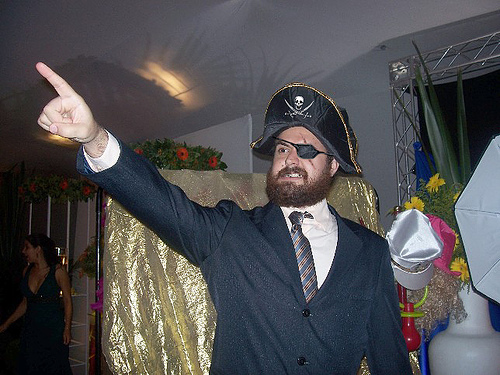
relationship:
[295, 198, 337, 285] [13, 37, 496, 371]
white shirt in photo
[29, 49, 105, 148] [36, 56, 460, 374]
hand of person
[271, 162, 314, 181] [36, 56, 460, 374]
mouth of person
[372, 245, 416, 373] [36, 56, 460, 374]
arm of person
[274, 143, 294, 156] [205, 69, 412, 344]
eye of person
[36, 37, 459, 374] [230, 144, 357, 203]
person wearing beard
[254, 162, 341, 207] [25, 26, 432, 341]
beard on person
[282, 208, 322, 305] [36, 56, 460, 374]
tie on person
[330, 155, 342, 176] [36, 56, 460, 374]
ear on person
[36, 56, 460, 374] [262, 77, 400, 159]
person wearing hat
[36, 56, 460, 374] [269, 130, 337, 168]
person wearing eye patch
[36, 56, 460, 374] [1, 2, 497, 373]
person inside house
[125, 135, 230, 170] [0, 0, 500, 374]
decoration in house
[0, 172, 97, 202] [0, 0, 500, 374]
decoration in house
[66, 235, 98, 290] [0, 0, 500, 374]
decoration in house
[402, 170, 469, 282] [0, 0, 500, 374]
decoration in house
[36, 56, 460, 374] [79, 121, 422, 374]
person wearing blazer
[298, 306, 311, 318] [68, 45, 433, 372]
button on blazer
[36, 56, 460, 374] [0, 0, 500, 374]
person in house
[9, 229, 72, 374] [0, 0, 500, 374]
woman in house